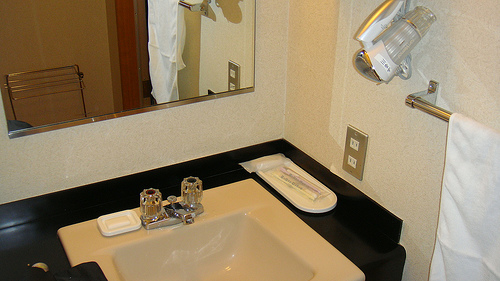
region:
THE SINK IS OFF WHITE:
[46, 170, 366, 280]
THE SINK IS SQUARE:
[50, 168, 361, 278]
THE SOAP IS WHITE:
[105, 214, 135, 233]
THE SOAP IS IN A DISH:
[105, 212, 138, 234]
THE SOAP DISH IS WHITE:
[84, 208, 151, 241]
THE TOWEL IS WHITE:
[420, 106, 497, 278]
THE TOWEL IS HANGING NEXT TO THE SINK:
[419, 99, 497, 279]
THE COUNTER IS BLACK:
[0, 135, 412, 280]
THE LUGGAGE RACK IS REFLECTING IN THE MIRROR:
[1, 54, 95, 142]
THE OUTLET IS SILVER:
[337, 120, 378, 185]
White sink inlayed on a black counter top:
[8, 170, 371, 250]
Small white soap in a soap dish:
[91, 206, 157, 241]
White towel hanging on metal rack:
[398, 75, 481, 275]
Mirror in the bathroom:
[90, 0, 262, 110]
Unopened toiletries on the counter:
[231, 146, 346, 241]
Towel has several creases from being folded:
[130, 10, 177, 92]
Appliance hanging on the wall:
[391, 0, 427, 90]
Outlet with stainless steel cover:
[330, 105, 366, 196]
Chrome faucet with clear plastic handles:
[127, 180, 223, 240]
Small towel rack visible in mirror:
[0, 57, 122, 144]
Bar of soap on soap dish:
[81, 200, 155, 238]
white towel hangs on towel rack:
[406, 88, 499, 279]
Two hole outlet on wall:
[337, 121, 374, 181]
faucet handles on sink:
[131, 170, 218, 235]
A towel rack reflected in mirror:
[5, 51, 127, 151]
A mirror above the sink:
[1, 0, 264, 147]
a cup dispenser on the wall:
[328, 13, 430, 113]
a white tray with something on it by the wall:
[242, 142, 339, 234]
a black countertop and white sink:
[2, 125, 447, 278]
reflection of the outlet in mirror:
[218, 55, 246, 95]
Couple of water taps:
[136, 172, 206, 228]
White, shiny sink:
[61, 212, 371, 277]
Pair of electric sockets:
[336, 118, 371, 181]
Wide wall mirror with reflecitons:
[1, 1, 281, 117]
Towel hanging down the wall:
[405, 90, 496, 280]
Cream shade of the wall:
[280, 6, 330, 126]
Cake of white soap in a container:
[95, 205, 140, 230]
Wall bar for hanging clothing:
[402, 85, 443, 130]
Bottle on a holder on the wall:
[342, 4, 446, 84]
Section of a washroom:
[4, 5, 494, 275]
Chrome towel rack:
[405, 70, 495, 156]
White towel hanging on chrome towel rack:
[412, 70, 492, 266]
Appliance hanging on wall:
[340, 12, 420, 87]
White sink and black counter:
[30, 187, 400, 277]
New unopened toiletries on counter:
[226, 132, 337, 213]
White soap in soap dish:
[92, 203, 152, 238]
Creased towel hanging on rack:
[138, 3, 198, 118]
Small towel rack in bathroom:
[3, 58, 111, 128]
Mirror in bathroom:
[42, 0, 268, 98]